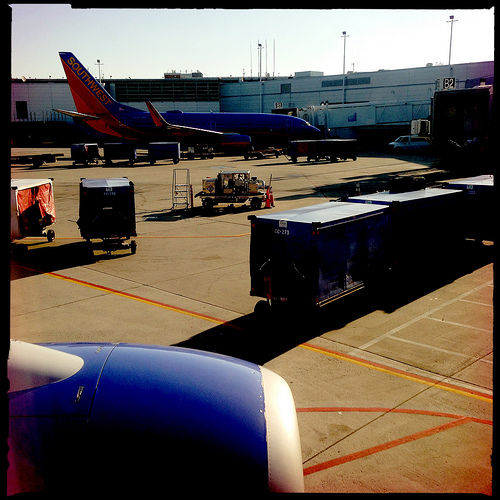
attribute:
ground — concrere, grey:
[23, 236, 254, 350]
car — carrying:
[66, 169, 173, 268]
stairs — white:
[156, 162, 201, 217]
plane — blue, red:
[39, 35, 326, 171]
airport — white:
[219, 66, 481, 160]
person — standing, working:
[248, 176, 262, 195]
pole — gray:
[325, 19, 361, 89]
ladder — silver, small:
[167, 161, 197, 212]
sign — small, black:
[269, 213, 286, 243]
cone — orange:
[259, 191, 281, 212]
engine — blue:
[197, 121, 252, 149]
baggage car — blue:
[77, 176, 138, 263]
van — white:
[391, 125, 428, 158]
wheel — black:
[180, 140, 203, 165]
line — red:
[364, 392, 427, 448]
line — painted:
[362, 322, 405, 354]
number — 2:
[52, 378, 99, 421]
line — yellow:
[106, 272, 140, 311]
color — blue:
[140, 345, 202, 406]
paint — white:
[343, 331, 387, 357]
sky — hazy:
[7, 9, 484, 72]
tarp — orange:
[25, 180, 57, 232]